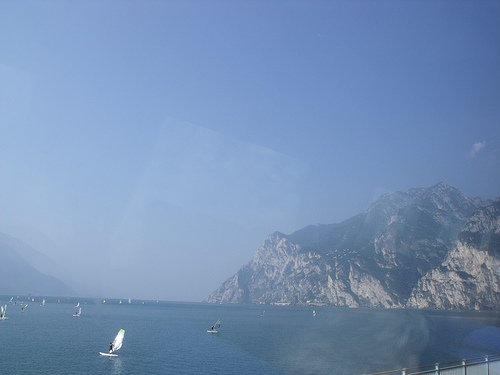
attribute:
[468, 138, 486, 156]
clouds — white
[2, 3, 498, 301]
sky — blue, white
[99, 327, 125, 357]
boat — white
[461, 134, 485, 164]
clouds — white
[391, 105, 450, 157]
sky — blue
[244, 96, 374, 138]
sky — blue, clear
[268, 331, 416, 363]
water — clear, blue, ocean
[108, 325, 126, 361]
sail — windsurfer, white, one